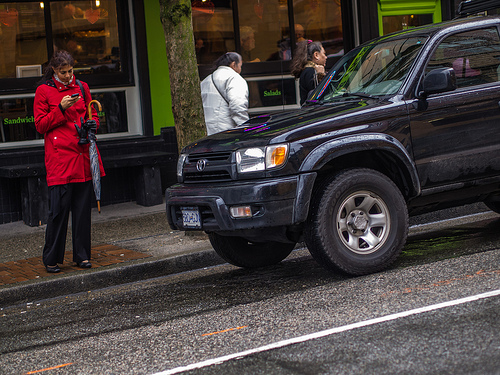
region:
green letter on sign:
[261, 87, 269, 100]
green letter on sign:
[266, 89, 272, 96]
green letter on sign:
[3, 115, 10, 125]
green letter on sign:
[8, 118, 13, 124]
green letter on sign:
[10, 115, 17, 125]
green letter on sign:
[14, 115, 21, 126]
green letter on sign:
[18, 115, 25, 124]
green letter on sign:
[20, 115, 34, 124]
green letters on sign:
[4, 113, 33, 129]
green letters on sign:
[260, 87, 288, 101]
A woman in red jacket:
[28, 50, 118, 275]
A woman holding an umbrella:
[28, 51, 113, 273]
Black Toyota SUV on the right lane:
[164, 18, 496, 305]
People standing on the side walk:
[3, 10, 355, 270]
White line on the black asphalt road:
[193, 255, 484, 373]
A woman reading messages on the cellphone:
[32, 44, 102, 137]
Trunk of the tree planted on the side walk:
[158, 3, 222, 148]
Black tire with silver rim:
[313, 168, 408, 278]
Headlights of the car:
[172, 140, 304, 173]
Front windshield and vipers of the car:
[316, 26, 438, 96]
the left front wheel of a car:
[305, 158, 415, 281]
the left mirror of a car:
[411, 63, 463, 111]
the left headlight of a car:
[233, 141, 270, 174]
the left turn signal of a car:
[264, 140, 293, 171]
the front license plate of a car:
[175, 201, 206, 234]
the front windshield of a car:
[321, 28, 431, 105]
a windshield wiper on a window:
[331, 85, 399, 106]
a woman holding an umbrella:
[75, 98, 116, 214]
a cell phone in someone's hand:
[57, 87, 85, 111]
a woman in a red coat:
[29, 72, 110, 195]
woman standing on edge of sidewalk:
[30, 44, 101, 275]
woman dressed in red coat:
[24, 46, 109, 279]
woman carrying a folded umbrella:
[31, 45, 111, 278]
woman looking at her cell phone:
[33, 43, 113, 273]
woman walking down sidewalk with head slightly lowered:
[202, 50, 252, 139]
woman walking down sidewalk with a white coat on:
[195, 49, 252, 134]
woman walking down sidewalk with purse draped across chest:
[196, 48, 251, 135]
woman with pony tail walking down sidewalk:
[279, 33, 332, 106]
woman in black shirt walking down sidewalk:
[288, 33, 332, 107]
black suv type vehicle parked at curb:
[158, 6, 495, 278]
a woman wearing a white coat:
[201, 51, 246, 134]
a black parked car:
[163, 14, 498, 278]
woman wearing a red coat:
[33, 75, 105, 185]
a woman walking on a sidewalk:
[199, 49, 248, 131]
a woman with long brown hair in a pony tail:
[289, 35, 328, 76]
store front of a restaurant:
[0, 0, 350, 155]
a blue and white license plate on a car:
[179, 203, 201, 230]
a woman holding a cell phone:
[61, 90, 79, 109]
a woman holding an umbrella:
[86, 99, 101, 216]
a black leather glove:
[73, 118, 90, 145]